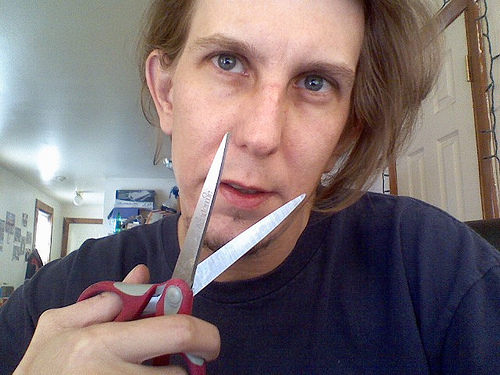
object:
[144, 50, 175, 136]
ears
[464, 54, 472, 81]
hinge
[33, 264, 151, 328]
finger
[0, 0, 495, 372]
woman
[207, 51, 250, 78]
eye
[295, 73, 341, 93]
eye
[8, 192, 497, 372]
shirt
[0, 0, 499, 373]
man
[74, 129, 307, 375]
scissors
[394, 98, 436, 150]
ground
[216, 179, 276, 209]
lips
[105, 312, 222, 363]
finger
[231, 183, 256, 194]
teeth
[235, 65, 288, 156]
nose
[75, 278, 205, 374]
handle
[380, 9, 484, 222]
door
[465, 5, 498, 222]
trim